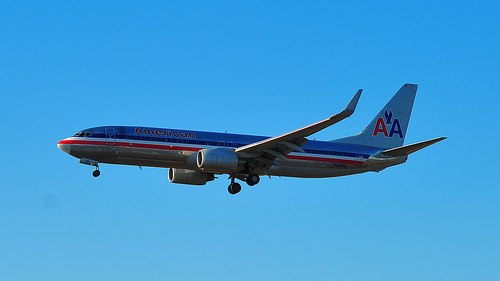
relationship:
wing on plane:
[237, 88, 366, 152] [57, 83, 447, 195]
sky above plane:
[2, 0, 481, 279] [57, 83, 447, 195]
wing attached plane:
[237, 117, 344, 152] [57, 107, 397, 189]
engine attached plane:
[194, 146, 242, 172] [28, 70, 472, 202]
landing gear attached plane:
[226, 170, 260, 195] [57, 83, 447, 195]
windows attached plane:
[73, 128, 92, 138] [57, 83, 447, 195]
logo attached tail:
[371, 107, 403, 139] [322, 82, 417, 149]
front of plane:
[53, 115, 148, 173] [40, 77, 457, 214]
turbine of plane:
[179, 137, 249, 174] [28, 63, 496, 224]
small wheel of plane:
[91, 169, 100, 178] [57, 83, 447, 195]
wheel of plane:
[225, 181, 247, 196] [57, 83, 447, 195]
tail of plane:
[362, 82, 448, 173] [53, 75, 450, 206]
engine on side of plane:
[189, 146, 258, 178] [15, 77, 485, 229]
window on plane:
[174, 122, 229, 152] [76, 44, 452, 204]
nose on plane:
[51, 133, 74, 156] [36, 75, 455, 244]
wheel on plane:
[225, 181, 243, 196] [57, 107, 397, 189]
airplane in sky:
[57, 82, 448, 195] [2, 0, 481, 279]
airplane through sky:
[54, 82, 448, 195] [1, 1, 304, 123]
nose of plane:
[58, 133, 74, 156] [38, 72, 448, 186]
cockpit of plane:
[62, 122, 110, 144] [38, 72, 448, 186]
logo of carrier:
[371, 107, 403, 139] [52, 82, 447, 193]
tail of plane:
[362, 82, 448, 173] [57, 83, 447, 195]